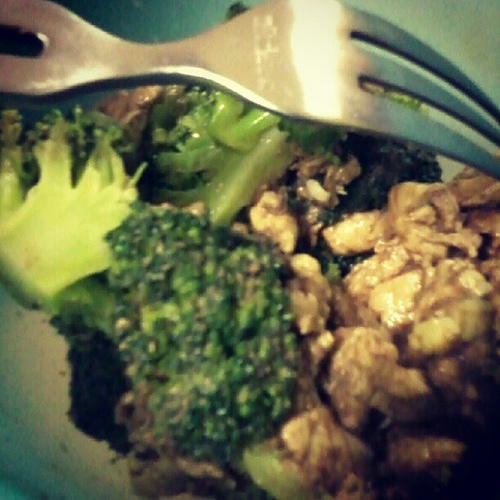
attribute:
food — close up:
[138, 164, 300, 278]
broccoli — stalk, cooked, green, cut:
[14, 209, 116, 245]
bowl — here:
[134, 16, 168, 31]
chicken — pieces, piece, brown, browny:
[359, 270, 397, 386]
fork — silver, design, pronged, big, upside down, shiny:
[155, 51, 415, 125]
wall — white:
[451, 1, 479, 24]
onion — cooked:
[77, 77, 141, 119]